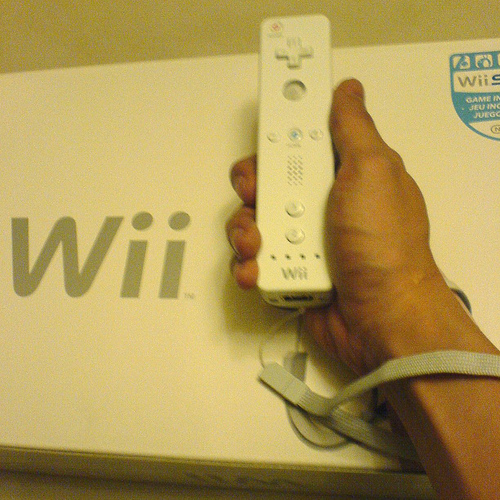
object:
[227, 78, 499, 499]
hand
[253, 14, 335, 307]
remote control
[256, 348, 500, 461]
strap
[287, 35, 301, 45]
up button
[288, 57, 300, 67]
down button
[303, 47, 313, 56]
right button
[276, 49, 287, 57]
left button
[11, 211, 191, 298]
word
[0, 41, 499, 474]
wii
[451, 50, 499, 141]
emblem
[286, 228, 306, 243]
buttons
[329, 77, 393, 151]
thumb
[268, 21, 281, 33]
power button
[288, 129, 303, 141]
home button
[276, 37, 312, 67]
d pad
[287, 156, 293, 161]
holes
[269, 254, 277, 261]
lights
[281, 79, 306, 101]
round button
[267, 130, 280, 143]
round buttons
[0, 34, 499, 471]
surface